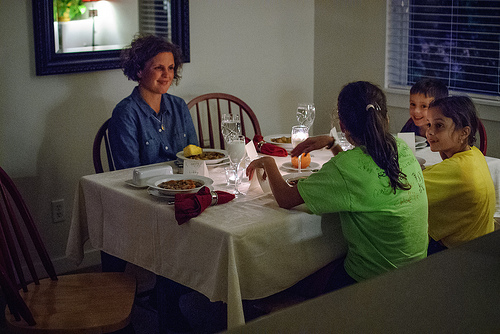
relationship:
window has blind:
[384, 0, 499, 123] [387, 1, 498, 101]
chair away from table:
[0, 167, 141, 333] [62, 133, 499, 333]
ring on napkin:
[209, 188, 218, 205] [173, 185, 235, 224]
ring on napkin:
[255, 139, 266, 153] [241, 132, 288, 159]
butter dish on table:
[122, 163, 172, 188] [62, 133, 499, 333]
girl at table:
[246, 80, 430, 295] [62, 133, 499, 333]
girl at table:
[420, 95, 497, 256] [62, 133, 499, 333]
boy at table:
[398, 77, 450, 148] [62, 133, 499, 333]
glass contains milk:
[223, 133, 247, 184] [227, 139, 246, 165]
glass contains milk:
[291, 124, 308, 153] [291, 132, 308, 148]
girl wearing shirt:
[246, 80, 430, 295] [297, 139, 429, 283]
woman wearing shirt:
[106, 32, 200, 169] [110, 84, 200, 168]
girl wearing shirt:
[420, 95, 497, 256] [422, 147, 496, 248]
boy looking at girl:
[398, 77, 450, 148] [246, 80, 430, 295]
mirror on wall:
[49, 0, 172, 56] [0, 0, 316, 273]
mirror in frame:
[49, 0, 172, 56] [30, 1, 193, 80]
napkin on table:
[173, 185, 235, 224] [62, 133, 499, 333]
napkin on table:
[241, 132, 288, 159] [62, 133, 499, 333]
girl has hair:
[246, 80, 430, 295] [336, 79, 411, 191]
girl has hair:
[420, 95, 497, 256] [427, 93, 479, 146]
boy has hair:
[398, 77, 450, 148] [408, 77, 451, 99]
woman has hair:
[106, 32, 200, 169] [117, 34, 183, 86]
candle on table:
[291, 151, 311, 168] [62, 133, 499, 333]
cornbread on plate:
[181, 144, 201, 157] [174, 147, 231, 163]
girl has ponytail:
[246, 80, 430, 295] [362, 106, 410, 193]